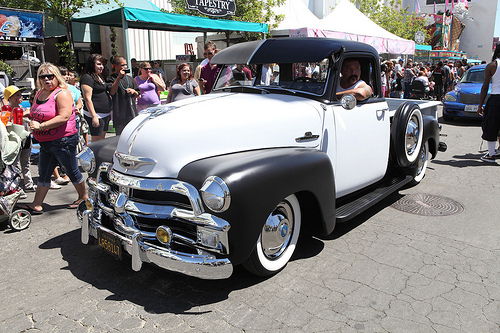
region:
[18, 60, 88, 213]
woman wearing pink tank top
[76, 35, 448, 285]
old black and white pickup on street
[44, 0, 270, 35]
green awning near pickup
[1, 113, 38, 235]
woman pushing baby stroller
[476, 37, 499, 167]
man wearing white tank top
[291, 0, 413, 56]
pink tent behind pickup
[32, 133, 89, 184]
woman wearing blue jean capris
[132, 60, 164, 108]
woman in purple shirt looking at truck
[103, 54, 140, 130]
man in black shirt taking picture of truck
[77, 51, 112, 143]
woman in black shirt standing next to man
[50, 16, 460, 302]
A black and white truck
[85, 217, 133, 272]
A license plate on a truck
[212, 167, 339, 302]
White wall tires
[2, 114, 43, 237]
A baby stroller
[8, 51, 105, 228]
A woman wearing a pink shirt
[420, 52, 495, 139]
A blue car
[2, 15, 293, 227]
A group of people looking at a truck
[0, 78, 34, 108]
Yellow baseball cap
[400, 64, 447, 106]
A person riding a scooter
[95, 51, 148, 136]
A young man wearing a necklace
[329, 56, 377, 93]
A man in a car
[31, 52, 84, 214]
A lady in a pink shirt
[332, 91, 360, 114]
A mirror of a car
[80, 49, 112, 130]
A girl in a black shirt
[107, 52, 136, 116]
A man in a black shirt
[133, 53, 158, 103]
A lady in a purple shirt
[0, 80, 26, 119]
A young boy in a yellow hat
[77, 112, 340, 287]
The front of an older car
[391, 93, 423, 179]
The spare tire of a car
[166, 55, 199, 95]
A lady in a grey shirt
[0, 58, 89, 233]
blond woman pushing a stroller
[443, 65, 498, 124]
blue modern front end of car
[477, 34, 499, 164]
man in black shorts and white undershirt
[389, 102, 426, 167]
spare tire for restored truck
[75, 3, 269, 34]
aqua blue awning over sidewalk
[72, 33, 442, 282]
early model restored pickup truck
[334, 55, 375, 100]
man driving restored truck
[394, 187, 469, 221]
manhole cover in middle of the street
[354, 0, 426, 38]
top of leafy green tree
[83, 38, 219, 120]
group of people looking at the restored truck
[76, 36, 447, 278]
old refurbished black and white pickup truck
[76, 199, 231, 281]
pickup truck has shiny silver bumper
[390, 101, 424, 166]
spare tire on pickup truck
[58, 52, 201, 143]
group of people look at pickup truck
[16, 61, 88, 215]
woman is walking next to pickup truck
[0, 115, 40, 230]
baby stroller pushed by woman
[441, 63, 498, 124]
blue car behind pickup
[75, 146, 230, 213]
pickup has two head lights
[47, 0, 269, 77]
green awning behind pickup truck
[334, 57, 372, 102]
man driving pickup truck